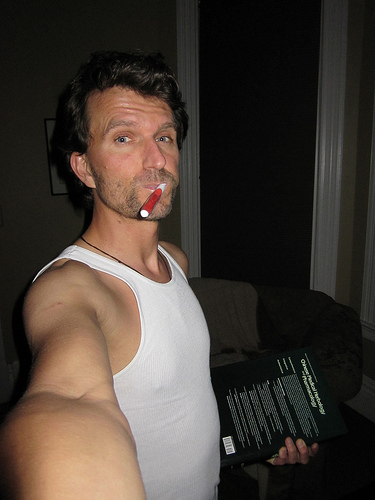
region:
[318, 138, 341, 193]
portion of white door trim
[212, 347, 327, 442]
man holding black book with white wording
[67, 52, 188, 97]
man's black wavy hair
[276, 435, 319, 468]
well manicured fingers holding book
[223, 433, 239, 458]
small white bar code on book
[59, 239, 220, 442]
man wearing white tee shirt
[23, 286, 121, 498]
muscular man's arm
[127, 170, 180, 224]
facial hair on man's face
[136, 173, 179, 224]
red and white toothbrush in man's mouth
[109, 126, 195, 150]
man's dark green eyes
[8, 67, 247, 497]
Man standing next a door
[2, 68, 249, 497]
Man with a toothbrush in his mouth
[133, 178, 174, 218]
White and red toothbrush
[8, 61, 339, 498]
Man holding a book in hos left arm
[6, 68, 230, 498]
Men wearing a white tank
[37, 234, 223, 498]
White tank on man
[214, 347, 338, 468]
Black book on hand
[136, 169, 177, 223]
Red and white toothbrush on mouth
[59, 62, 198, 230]
Head of man with thoothbrush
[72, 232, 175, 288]
Necklace of man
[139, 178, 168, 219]
a toothbrush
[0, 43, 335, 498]
a man taking a selfie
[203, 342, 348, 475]
a black book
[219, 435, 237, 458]
a white bar code on a black book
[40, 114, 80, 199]
a picture behind the man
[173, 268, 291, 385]
a brown blanket on a sofa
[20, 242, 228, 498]
a white tank top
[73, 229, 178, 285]
a necklace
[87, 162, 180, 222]
razor stubble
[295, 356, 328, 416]
title of book in white letters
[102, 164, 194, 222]
a mans beard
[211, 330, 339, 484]
a book in the mans hands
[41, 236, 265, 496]
a white tank top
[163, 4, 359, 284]
a door way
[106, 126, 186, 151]
mans blue eyes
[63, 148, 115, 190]
a mans ear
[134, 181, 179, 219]
a red and white tooth brush in the mans mouth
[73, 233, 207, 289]
a necklace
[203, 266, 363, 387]
a brown chair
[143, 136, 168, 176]
a mans noes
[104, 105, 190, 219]
the guy is holding a marker in his mouth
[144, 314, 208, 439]
the guy wearing white shirt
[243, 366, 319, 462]
a man holding a book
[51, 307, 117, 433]
the man works out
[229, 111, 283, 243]
the lights turned off in the room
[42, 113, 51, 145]
there picture frame behind the man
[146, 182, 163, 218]
the marker is red and white color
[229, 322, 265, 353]
guy standing near the coach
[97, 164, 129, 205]
man didn't shave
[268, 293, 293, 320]
there something on the bed